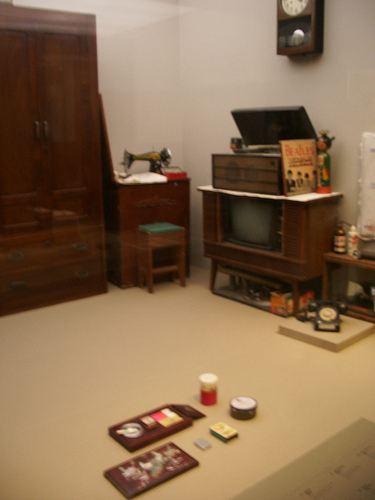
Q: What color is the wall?
A: White.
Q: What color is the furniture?
A: Brown.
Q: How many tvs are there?
A: 1.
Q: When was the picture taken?
A: When the lights were on.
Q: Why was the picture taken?
A: To show the room.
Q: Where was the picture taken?
A: In a living room.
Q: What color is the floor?
A: Beige.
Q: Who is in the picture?
A: No one.